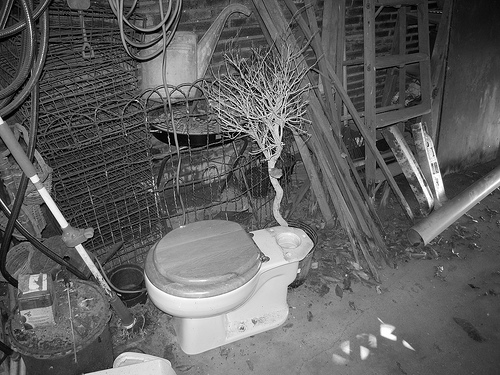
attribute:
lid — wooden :
[152, 216, 261, 288]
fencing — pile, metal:
[37, 77, 291, 291]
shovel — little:
[66, 2, 104, 64]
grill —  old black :
[133, 96, 269, 206]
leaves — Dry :
[329, 242, 491, 359]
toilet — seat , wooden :
[118, 189, 380, 373]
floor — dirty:
[2, 162, 497, 373]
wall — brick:
[133, 0, 272, 94]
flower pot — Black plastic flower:
[103, 264, 155, 310]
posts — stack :
[244, 2, 414, 284]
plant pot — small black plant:
[104, 257, 159, 315]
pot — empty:
[103, 255, 160, 312]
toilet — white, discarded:
[83, 175, 376, 355]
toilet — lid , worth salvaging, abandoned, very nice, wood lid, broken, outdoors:
[139, 215, 316, 355]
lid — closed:
[144, 218, 265, 297]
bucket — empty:
[104, 275, 144, 309]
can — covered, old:
[131, 20, 211, 90]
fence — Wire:
[37, 92, 289, 227]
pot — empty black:
[99, 257, 163, 304]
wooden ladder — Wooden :
[334, 3, 376, 190]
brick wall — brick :
[2, 1, 497, 278]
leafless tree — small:
[198, 24, 308, 230]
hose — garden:
[0, 2, 52, 280]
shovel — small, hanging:
[64, 10, 114, 63]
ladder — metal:
[249, 12, 433, 277]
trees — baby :
[205, 61, 316, 260]